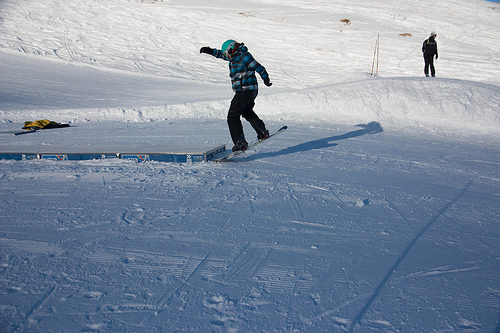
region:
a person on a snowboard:
[178, 36, 300, 168]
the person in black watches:
[418, 25, 440, 77]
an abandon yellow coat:
[10, 103, 70, 141]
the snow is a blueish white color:
[140, 195, 336, 318]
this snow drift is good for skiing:
[322, 70, 472, 130]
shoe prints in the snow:
[252, 262, 317, 318]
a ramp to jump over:
[90, 135, 225, 185]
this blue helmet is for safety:
[218, 35, 238, 58]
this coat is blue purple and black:
[200, 42, 285, 93]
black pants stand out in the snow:
[210, 86, 269, 143]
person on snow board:
[200, 8, 283, 155]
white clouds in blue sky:
[25, 7, 60, 49]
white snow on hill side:
[85, 197, 118, 237]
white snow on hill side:
[331, 202, 394, 262]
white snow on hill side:
[240, 205, 295, 261]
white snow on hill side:
[140, 231, 201, 301]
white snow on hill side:
[105, 178, 158, 231]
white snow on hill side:
[115, 75, 176, 116]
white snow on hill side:
[303, 75, 354, 108]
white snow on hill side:
[347, 222, 399, 266]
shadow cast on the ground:
[279, 114, 390, 157]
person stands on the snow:
[413, 25, 447, 85]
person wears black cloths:
[416, 26, 443, 79]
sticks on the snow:
[365, 30, 388, 77]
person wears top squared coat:
[191, 31, 281, 154]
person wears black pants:
[198, 37, 279, 155]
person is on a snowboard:
[188, 27, 299, 163]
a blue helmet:
[214, 29, 249, 66]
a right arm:
[191, 39, 224, 65]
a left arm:
[245, 56, 279, 91]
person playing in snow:
[185, 28, 267, 153]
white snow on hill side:
[52, 28, 102, 66]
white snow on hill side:
[218, 232, 268, 272]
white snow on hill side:
[87, 226, 151, 267]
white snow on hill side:
[387, 142, 429, 172]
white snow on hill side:
[170, 191, 240, 266]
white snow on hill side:
[298, 32, 350, 87]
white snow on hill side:
[322, 215, 380, 257]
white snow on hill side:
[88, 198, 220, 260]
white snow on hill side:
[310, 172, 380, 230]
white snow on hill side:
[368, 181, 430, 233]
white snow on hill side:
[108, 46, 160, 94]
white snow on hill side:
[344, 208, 428, 285]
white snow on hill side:
[112, 246, 210, 308]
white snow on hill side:
[258, 166, 319, 237]